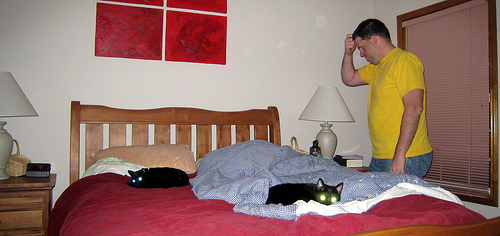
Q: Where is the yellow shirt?
A: On the man.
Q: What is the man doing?
A: Scratching his head.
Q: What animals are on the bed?
A: Cats.